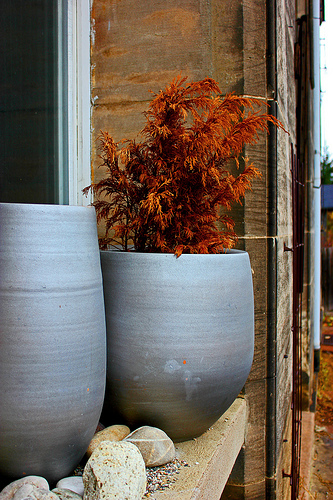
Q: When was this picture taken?
A: During daylight.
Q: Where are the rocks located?
A: In front of the flower.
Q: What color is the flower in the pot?
A: Orange and Red.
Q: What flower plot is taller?
A: The one on the left.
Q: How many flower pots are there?
A: 2.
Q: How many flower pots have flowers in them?
A: 1.